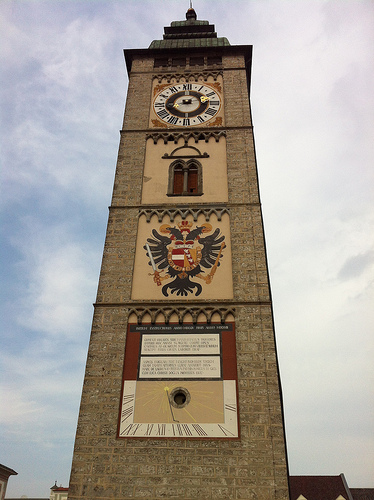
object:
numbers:
[158, 79, 202, 93]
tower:
[85, 29, 300, 464]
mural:
[130, 214, 235, 301]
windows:
[166, 159, 204, 197]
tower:
[71, 47, 323, 498]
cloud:
[9, 213, 108, 355]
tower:
[65, 0, 291, 499]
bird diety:
[131, 210, 234, 300]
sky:
[0, 2, 372, 495]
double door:
[173, 163, 198, 193]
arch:
[161, 144, 209, 160]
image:
[165, 387, 191, 422]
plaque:
[115, 376, 240, 442]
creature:
[206, 117, 222, 127]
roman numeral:
[183, 83, 192, 90]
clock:
[154, 82, 222, 126]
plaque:
[123, 321, 235, 382]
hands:
[174, 97, 210, 108]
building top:
[147, 3, 229, 49]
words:
[142, 337, 218, 376]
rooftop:
[289, 473, 373, 500]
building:
[289, 473, 352, 499]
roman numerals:
[155, 84, 219, 125]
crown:
[178, 220, 193, 229]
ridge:
[93, 299, 271, 305]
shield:
[143, 220, 226, 297]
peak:
[183, 1, 197, 20]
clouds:
[263, 41, 365, 311]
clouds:
[256, 0, 372, 477]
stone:
[84, 364, 113, 376]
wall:
[69, 53, 291, 500]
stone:
[84, 379, 103, 389]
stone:
[76, 409, 107, 419]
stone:
[78, 399, 109, 411]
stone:
[78, 399, 105, 414]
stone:
[76, 424, 103, 436]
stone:
[72, 446, 95, 454]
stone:
[78, 401, 109, 411]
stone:
[76, 434, 94, 443]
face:
[153, 84, 218, 126]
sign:
[119, 324, 239, 439]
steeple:
[169, 1, 209, 25]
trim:
[149, 72, 225, 127]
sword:
[145, 243, 164, 286]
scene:
[0, 1, 372, 499]